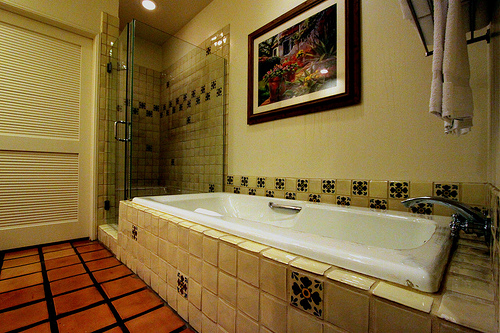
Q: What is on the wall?
A: A painting.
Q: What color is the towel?
A: White.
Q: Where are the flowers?
A: In the painting.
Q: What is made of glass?
A: The shower.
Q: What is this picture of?
A: A shower and tub.